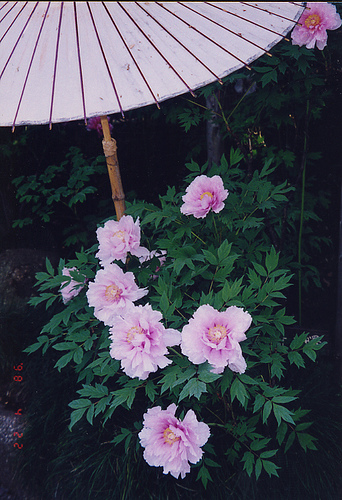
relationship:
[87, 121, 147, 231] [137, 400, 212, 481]
stick above flower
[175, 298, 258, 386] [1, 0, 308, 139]
flower behind umbrella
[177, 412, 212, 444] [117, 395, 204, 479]
petals on flower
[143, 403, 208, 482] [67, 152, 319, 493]
flower on tree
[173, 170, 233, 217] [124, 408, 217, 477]
petal on flower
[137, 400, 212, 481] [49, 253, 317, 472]
flower in bush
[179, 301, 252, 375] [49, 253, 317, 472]
flower in bush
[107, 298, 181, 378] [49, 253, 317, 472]
flower in bush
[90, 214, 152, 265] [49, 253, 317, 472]
flower in bush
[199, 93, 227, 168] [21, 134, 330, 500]
trunk behind tree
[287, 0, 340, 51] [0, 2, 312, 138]
flower behind umbrella brim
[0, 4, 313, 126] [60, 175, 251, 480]
umbrella over flowers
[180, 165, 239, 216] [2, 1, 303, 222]
flower under umbrella